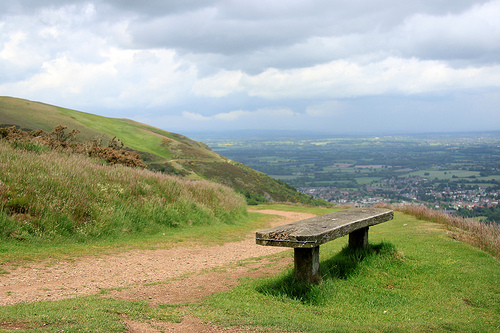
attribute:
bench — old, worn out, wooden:
[259, 185, 376, 286]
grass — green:
[203, 202, 499, 331]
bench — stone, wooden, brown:
[255, 202, 393, 292]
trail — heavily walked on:
[1, 205, 318, 307]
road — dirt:
[0, 201, 325, 309]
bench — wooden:
[249, 198, 401, 283]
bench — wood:
[258, 208, 393, 280]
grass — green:
[1, 128, 266, 260]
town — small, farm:
[207, 140, 499, 210]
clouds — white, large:
[24, 9, 481, 111]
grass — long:
[0, 93, 325, 253]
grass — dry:
[1, 129, 248, 218]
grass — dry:
[381, 195, 498, 255]